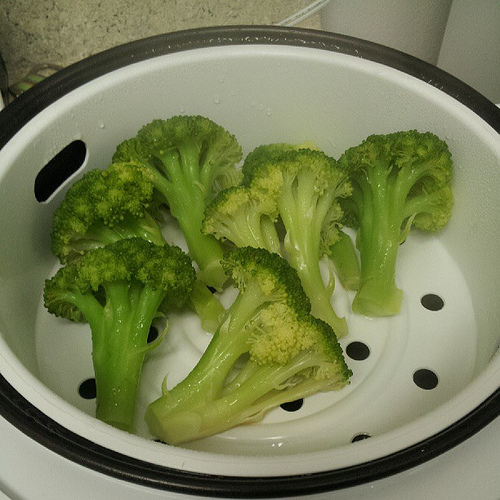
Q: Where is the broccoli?
A: In the colander.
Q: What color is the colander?
A: White.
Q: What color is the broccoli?
A: Green.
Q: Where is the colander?
A: In the pot.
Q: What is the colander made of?
A: Plastic.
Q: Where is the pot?
A: Under the colander.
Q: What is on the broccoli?
A: Water.